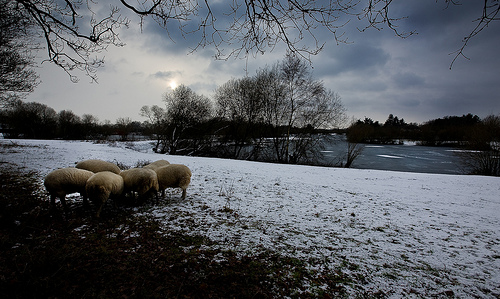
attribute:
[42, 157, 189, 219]
sheep — grazing, tailless, eating, sheared, gathered, white, together, grouped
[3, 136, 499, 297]
snow — white, melting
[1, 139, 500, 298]
ground — snow covered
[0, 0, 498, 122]
sky — blue, stormy, grey, cloudy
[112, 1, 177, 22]
limb — small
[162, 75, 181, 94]
sun — shining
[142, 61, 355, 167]
trees — leafless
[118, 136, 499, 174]
water — frozen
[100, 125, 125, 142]
house — small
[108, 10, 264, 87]
clouds — gray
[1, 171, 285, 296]
leaves — brown